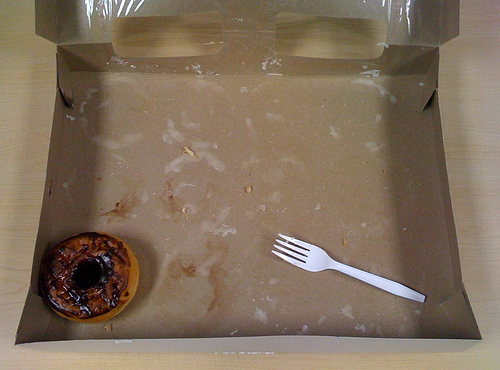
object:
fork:
[271, 233, 427, 305]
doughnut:
[39, 232, 139, 324]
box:
[10, 1, 484, 355]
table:
[0, 0, 499, 369]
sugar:
[160, 148, 230, 175]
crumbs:
[180, 146, 203, 161]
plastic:
[54, 0, 444, 59]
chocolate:
[42, 232, 131, 320]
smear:
[95, 180, 143, 227]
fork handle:
[331, 261, 427, 304]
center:
[70, 256, 104, 289]